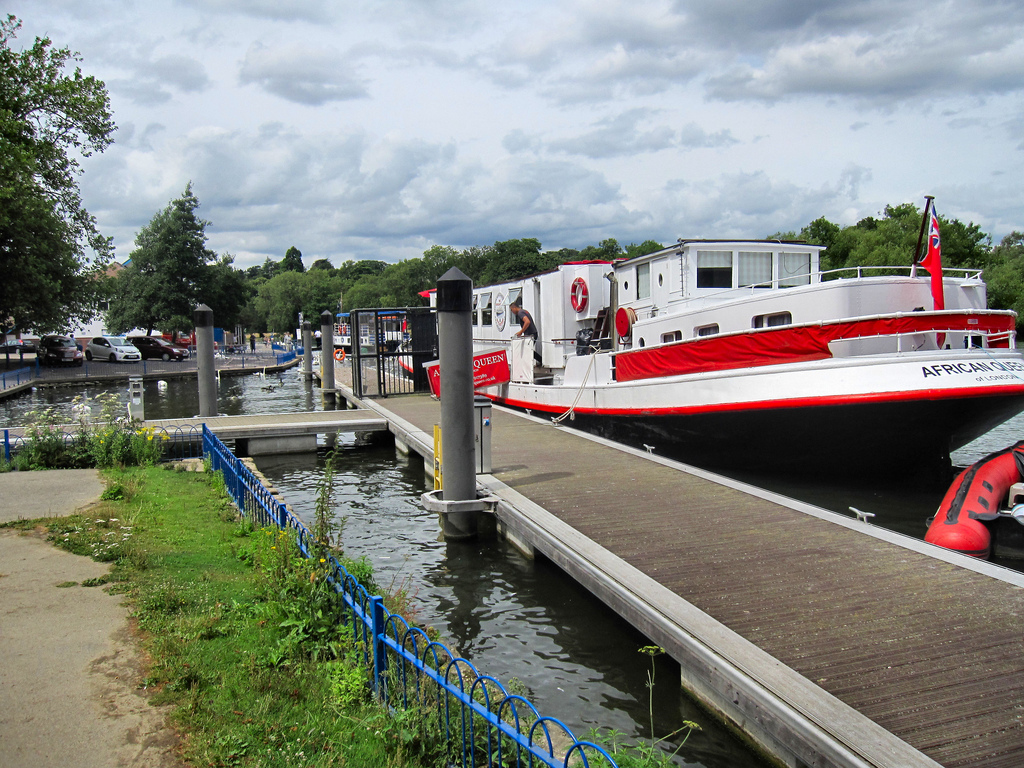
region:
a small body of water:
[1, 360, 767, 766]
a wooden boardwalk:
[307, 344, 1022, 762]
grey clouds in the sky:
[5, 4, 1020, 270]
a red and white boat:
[416, 209, 1021, 488]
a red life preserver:
[560, 265, 596, 319]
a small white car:
[80, 329, 147, 369]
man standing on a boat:
[471, 269, 1022, 478]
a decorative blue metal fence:
[194, 424, 628, 766]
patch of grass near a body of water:
[65, 433, 756, 766]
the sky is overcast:
[122, 1, 832, 185]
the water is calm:
[419, 529, 596, 701]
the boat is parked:
[497, 198, 994, 449]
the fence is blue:
[206, 555, 527, 717]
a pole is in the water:
[389, 254, 519, 550]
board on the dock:
[517, 426, 537, 443]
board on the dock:
[588, 449, 604, 463]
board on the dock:
[655, 505, 688, 522]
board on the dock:
[399, 383, 423, 397]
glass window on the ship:
[690, 248, 730, 288]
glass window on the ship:
[734, 248, 767, 288]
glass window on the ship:
[776, 254, 809, 289]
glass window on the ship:
[762, 305, 792, 328]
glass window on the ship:
[750, 314, 761, 327]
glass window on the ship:
[691, 318, 712, 337]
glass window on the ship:
[633, 334, 643, 350]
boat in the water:
[391, 211, 1014, 458]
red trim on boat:
[527, 358, 1022, 454]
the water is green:
[274, 440, 568, 712]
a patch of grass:
[48, 417, 425, 766]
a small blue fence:
[174, 408, 607, 762]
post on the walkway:
[392, 234, 513, 542]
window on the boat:
[672, 238, 809, 290]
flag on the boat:
[895, 170, 975, 322]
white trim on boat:
[519, 345, 1007, 415]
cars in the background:
[23, 303, 194, 373]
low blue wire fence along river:
[206, 437, 619, 766]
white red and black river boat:
[421, 262, 1022, 479]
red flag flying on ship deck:
[907, 200, 950, 325]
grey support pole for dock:
[430, 270, 488, 569]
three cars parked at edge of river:
[41, 330, 181, 365]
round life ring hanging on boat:
[570, 267, 591, 315]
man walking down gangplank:
[504, 297, 542, 370]